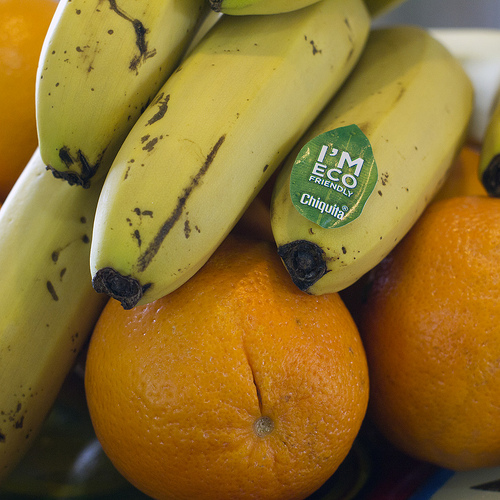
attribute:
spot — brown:
[42, 275, 62, 305]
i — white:
[312, 144, 332, 164]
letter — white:
[308, 162, 325, 179]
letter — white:
[342, 175, 359, 190]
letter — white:
[338, 150, 361, 176]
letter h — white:
[306, 192, 318, 209]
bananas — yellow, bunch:
[260, 0, 477, 295]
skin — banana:
[221, 60, 283, 101]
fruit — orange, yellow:
[4, 2, 498, 483]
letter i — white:
[309, 140, 334, 166]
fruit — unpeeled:
[82, 235, 369, 499]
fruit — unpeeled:
[370, 198, 498, 479]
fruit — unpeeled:
[36, 0, 174, 189]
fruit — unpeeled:
[0, 170, 110, 481]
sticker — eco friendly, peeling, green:
[287, 118, 380, 231]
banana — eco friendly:
[112, 25, 463, 344]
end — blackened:
[279, 240, 324, 288]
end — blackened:
[94, 258, 144, 307]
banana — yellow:
[269, 15, 481, 288]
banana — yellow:
[90, 0, 362, 295]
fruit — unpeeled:
[274, 21, 473, 286]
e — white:
[306, 158, 330, 185]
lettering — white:
[314, 138, 368, 197]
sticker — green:
[286, 122, 374, 236]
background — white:
[441, 0, 484, 52]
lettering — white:
[292, 194, 348, 223]